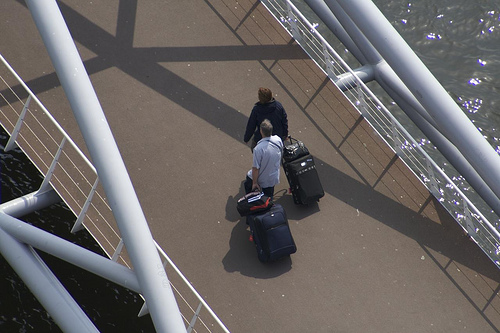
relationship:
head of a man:
[257, 86, 277, 105] [236, 85, 301, 152]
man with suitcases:
[241, 84, 290, 155] [236, 141, 335, 271]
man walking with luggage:
[241, 84, 290, 155] [236, 141, 335, 271]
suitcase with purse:
[283, 154, 327, 210] [280, 134, 311, 163]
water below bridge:
[414, 5, 500, 73] [1, 1, 493, 332]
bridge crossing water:
[1, 1, 493, 332] [414, 5, 500, 73]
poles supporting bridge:
[3, 200, 127, 332] [1, 1, 493, 332]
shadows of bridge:
[76, 9, 255, 117] [1, 1, 493, 332]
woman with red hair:
[236, 85, 301, 152] [264, 94, 270, 102]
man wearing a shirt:
[229, 118, 299, 205] [245, 134, 284, 190]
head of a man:
[260, 124, 274, 138] [229, 118, 299, 205]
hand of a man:
[250, 182, 260, 191] [229, 118, 299, 205]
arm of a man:
[248, 146, 264, 184] [229, 118, 299, 205]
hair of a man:
[267, 128, 272, 133] [229, 118, 299, 205]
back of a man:
[263, 145, 279, 178] [229, 118, 299, 205]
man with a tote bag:
[229, 118, 299, 205] [234, 188, 274, 218]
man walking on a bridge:
[236, 85, 301, 152] [1, 1, 493, 332]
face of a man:
[261, 121, 265, 137] [229, 118, 299, 205]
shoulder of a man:
[251, 138, 274, 155] [229, 118, 299, 205]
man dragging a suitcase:
[236, 85, 301, 152] [283, 154, 327, 210]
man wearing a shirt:
[229, 118, 299, 205] [257, 145, 278, 183]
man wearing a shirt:
[236, 85, 301, 152] [245, 134, 284, 190]